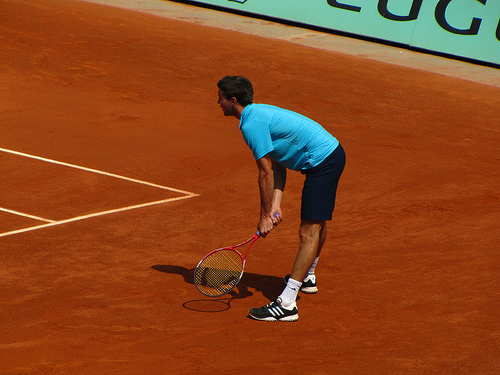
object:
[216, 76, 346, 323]
man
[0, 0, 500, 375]
tennis court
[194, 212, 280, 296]
tennis racket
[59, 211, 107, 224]
lines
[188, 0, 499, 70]
advertisement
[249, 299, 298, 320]
shoe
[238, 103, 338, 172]
shirt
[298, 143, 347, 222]
shorts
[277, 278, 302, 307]
socks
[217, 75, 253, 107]
hair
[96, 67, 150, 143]
ground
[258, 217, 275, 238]
hand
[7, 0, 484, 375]
photo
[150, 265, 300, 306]
shadow